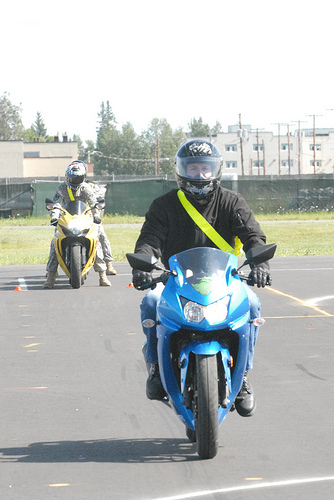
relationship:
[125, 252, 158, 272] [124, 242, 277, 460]
mirror on bike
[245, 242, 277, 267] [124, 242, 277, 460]
mirror on bike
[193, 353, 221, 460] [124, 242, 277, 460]
wheel on bike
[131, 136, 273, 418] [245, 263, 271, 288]
man wearing glove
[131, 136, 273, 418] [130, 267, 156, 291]
man wearing glove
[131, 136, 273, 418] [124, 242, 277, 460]
man on bike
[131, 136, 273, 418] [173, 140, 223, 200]
man wearing helmet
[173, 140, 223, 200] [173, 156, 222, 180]
helmet has visor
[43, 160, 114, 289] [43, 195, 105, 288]
man on motor bike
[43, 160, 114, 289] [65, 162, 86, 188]
man wearing helmet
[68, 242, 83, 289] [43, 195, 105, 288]
tire on motor bike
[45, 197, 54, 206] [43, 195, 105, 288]
mirror on motor bike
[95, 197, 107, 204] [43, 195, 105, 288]
mirror on motor bike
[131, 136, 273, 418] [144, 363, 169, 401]
man wearing boot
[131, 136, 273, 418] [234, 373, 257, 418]
man wearing boot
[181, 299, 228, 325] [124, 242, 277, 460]
headlight on bike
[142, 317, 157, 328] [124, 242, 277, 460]
turn signal on bike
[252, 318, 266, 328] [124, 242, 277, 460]
turn signal on bike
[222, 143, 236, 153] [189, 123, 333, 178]
window on building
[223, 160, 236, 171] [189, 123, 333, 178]
window on building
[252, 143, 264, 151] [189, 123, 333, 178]
window on building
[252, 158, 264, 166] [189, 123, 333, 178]
window on building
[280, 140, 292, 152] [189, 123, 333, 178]
window on building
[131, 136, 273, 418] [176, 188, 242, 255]
man has strap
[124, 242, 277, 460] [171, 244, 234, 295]
bike has windshield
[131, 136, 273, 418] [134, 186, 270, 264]
man wearing jacket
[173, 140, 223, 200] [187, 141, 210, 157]
helmet has emblem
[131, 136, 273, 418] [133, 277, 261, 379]
man in jeans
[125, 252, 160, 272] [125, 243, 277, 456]
mirror of motorbike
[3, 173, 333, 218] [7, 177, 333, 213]
fence in tarp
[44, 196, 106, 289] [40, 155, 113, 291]
motor bike with riders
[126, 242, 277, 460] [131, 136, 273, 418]
bike with man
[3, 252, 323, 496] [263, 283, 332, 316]
pavement with line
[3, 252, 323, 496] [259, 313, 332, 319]
pavement with line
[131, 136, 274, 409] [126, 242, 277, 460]
man with bike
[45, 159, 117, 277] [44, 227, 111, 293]
passenger wearing pants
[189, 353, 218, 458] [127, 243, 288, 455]
wheel of motorcycle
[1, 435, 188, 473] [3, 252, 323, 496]
shadow on pavement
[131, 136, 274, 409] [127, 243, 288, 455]
man riding motorcycle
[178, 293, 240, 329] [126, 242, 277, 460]
headlights on bike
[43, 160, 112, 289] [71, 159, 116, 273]
man with passenger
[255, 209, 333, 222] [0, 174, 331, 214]
grass near fence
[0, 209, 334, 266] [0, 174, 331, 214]
grass near fence